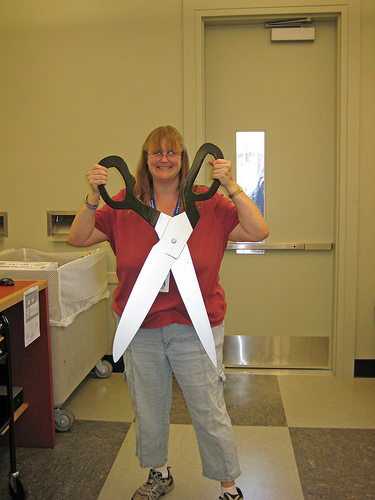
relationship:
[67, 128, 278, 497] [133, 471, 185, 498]
woman wearing sneakers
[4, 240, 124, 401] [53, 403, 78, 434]
bin with wheels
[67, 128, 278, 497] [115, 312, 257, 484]
woman wearing pants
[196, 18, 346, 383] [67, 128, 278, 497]
door behind woman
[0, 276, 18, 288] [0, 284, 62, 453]
mouse on desk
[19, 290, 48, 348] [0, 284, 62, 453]
paper hanging from desk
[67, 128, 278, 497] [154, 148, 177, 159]
woman wearing glasses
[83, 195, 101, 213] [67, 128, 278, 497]
wristwatch on woman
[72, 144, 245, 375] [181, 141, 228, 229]
shears with handles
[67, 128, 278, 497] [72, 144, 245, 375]
woman holding shears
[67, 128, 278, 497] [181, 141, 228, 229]
woman holding handles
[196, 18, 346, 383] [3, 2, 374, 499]
door to room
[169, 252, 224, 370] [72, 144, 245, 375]
blade on shears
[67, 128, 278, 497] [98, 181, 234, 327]
woman in shirt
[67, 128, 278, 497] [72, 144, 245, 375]
woman holding scissors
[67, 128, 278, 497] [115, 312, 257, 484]
woman wearing jeans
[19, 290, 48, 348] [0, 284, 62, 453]
paper attached to desk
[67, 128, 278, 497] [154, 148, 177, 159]
woman has glasses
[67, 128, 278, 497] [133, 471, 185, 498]
woman has sneakers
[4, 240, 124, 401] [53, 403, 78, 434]
bin has wheels